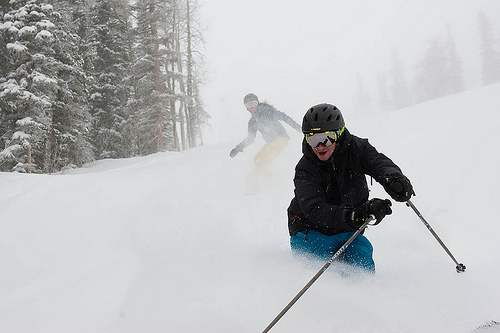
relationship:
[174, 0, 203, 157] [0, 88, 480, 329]
tree on field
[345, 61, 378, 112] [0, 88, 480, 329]
tree in field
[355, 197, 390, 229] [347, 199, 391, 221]
glove on hand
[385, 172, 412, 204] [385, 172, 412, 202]
glove on hand